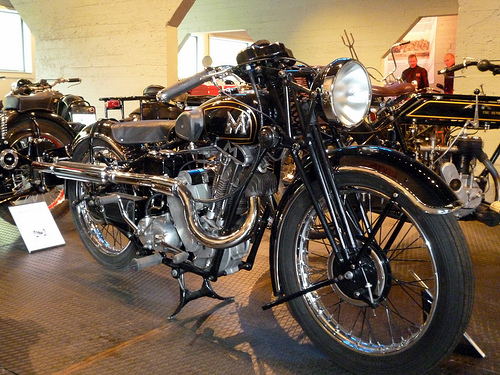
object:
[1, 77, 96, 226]
motorcycles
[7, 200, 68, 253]
object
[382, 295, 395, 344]
spokes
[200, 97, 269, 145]
tank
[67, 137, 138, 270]
tire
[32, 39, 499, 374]
bike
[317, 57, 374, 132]
headlight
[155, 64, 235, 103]
bar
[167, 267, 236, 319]
kickstand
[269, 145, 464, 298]
fender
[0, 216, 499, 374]
ground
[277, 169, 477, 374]
tire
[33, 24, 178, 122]
wall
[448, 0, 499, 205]
wall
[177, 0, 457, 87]
wall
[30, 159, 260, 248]
muffler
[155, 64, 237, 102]
handlebars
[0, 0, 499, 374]
building